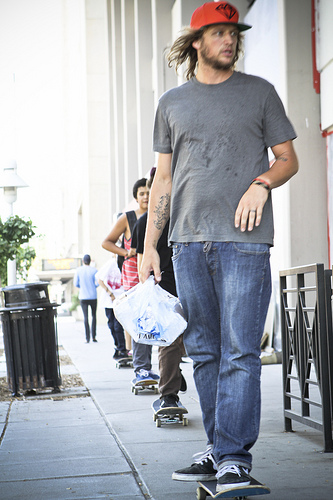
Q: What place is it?
A: It is a city.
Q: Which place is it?
A: It is a city.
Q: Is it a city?
A: Yes, it is a city.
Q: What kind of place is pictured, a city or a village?
A: It is a city.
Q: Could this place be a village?
A: No, it is a city.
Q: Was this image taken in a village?
A: No, the picture was taken in a city.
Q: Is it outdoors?
A: Yes, it is outdoors.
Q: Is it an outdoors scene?
A: Yes, it is outdoors.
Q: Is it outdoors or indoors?
A: It is outdoors.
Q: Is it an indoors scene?
A: No, it is outdoors.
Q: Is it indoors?
A: No, it is outdoors.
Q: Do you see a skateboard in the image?
A: Yes, there is a skateboard.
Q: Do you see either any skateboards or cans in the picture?
A: Yes, there is a skateboard.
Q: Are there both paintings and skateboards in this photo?
A: No, there is a skateboard but no paintings.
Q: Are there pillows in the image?
A: No, there are no pillows.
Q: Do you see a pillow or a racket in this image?
A: No, there are no pillows or rackets.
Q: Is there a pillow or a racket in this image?
A: No, there are no pillows or rackets.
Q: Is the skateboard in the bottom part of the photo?
A: Yes, the skateboard is in the bottom of the image.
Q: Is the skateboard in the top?
A: No, the skateboard is in the bottom of the image.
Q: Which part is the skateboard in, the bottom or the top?
A: The skateboard is in the bottom of the image.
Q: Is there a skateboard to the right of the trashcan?
A: Yes, there is a skateboard to the right of the trashcan.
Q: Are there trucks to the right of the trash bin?
A: No, there is a skateboard to the right of the trash bin.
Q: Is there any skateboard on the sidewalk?
A: Yes, there is a skateboard on the sidewalk.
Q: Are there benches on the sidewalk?
A: No, there is a skateboard on the sidewalk.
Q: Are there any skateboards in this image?
A: Yes, there is a skateboard.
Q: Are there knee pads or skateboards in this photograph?
A: Yes, there is a skateboard.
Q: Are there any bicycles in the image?
A: No, there are no bicycles.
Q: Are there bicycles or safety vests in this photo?
A: No, there are no bicycles or safety vests.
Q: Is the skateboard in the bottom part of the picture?
A: Yes, the skateboard is in the bottom of the image.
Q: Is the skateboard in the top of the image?
A: No, the skateboard is in the bottom of the image.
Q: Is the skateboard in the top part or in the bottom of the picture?
A: The skateboard is in the bottom of the image.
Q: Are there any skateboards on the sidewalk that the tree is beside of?
A: Yes, there is a skateboard on the side walk.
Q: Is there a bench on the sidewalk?
A: No, there is a skateboard on the sidewalk.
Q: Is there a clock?
A: No, there are no clocks.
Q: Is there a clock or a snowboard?
A: No, there are no clocks or snowboards.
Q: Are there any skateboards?
A: Yes, there is a skateboard.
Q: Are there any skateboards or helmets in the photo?
A: Yes, there is a skateboard.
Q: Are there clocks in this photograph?
A: No, there are no clocks.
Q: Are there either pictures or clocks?
A: No, there are no clocks or pictures.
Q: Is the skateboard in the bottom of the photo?
A: Yes, the skateboard is in the bottom of the image.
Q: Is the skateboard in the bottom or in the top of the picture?
A: The skateboard is in the bottom of the image.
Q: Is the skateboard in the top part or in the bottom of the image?
A: The skateboard is in the bottom of the image.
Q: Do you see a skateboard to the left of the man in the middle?
A: Yes, there is a skateboard to the left of the man.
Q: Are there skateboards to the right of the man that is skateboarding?
A: No, the skateboard is to the left of the man.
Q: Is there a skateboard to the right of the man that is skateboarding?
A: No, the skateboard is to the left of the man.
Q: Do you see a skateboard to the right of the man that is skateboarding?
A: No, the skateboard is to the left of the man.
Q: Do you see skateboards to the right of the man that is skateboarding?
A: No, the skateboard is to the left of the man.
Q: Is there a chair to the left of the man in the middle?
A: No, there is a skateboard to the left of the man.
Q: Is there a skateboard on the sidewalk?
A: Yes, there is a skateboard on the sidewalk.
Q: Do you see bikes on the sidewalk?
A: No, there is a skateboard on the sidewalk.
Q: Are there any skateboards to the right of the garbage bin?
A: Yes, there is a skateboard to the right of the garbage bin.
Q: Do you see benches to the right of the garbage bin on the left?
A: No, there is a skateboard to the right of the trash can.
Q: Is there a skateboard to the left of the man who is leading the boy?
A: Yes, there is a skateboard to the left of the man.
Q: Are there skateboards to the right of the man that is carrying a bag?
A: No, the skateboard is to the left of the man.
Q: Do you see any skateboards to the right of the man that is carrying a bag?
A: No, the skateboard is to the left of the man.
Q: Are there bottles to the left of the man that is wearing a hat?
A: No, there is a skateboard to the left of the man.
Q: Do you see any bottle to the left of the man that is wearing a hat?
A: No, there is a skateboard to the left of the man.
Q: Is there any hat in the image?
A: Yes, there is a hat.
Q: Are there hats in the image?
A: Yes, there is a hat.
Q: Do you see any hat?
A: Yes, there is a hat.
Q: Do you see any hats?
A: Yes, there is a hat.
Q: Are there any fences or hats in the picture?
A: Yes, there is a hat.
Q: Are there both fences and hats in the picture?
A: Yes, there are both a hat and a fence.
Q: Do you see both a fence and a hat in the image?
A: Yes, there are both a hat and a fence.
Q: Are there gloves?
A: No, there are no gloves.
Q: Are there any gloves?
A: No, there are no gloves.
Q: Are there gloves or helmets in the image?
A: No, there are no gloves or helmets.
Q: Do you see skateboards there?
A: Yes, there is a skateboard.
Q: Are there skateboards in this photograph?
A: Yes, there is a skateboard.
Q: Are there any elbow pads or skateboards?
A: Yes, there is a skateboard.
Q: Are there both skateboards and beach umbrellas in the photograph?
A: No, there is a skateboard but no beach umbrellas.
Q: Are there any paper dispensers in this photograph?
A: No, there are no paper dispensers.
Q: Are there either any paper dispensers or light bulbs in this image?
A: No, there are no paper dispensers or light bulbs.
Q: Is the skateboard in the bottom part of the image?
A: Yes, the skateboard is in the bottom of the image.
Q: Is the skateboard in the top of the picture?
A: No, the skateboard is in the bottom of the image.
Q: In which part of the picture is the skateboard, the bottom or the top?
A: The skateboard is in the bottom of the image.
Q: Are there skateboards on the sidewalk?
A: Yes, there is a skateboard on the sidewalk.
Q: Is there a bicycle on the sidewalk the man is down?
A: No, there is a skateboard on the side walk.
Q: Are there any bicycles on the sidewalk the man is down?
A: No, there is a skateboard on the side walk.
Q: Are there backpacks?
A: Yes, there is a backpack.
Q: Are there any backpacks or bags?
A: Yes, there is a backpack.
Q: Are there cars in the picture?
A: No, there are no cars.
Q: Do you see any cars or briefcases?
A: No, there are no cars or briefcases.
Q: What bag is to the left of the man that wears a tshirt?
A: The bag is a backpack.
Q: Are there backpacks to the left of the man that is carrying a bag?
A: Yes, there is a backpack to the left of the man.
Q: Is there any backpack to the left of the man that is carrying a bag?
A: Yes, there is a backpack to the left of the man.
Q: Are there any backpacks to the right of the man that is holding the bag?
A: No, the backpack is to the left of the man.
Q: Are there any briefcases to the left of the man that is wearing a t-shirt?
A: No, there is a backpack to the left of the man.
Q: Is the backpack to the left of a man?
A: Yes, the backpack is to the left of a man.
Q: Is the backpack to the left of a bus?
A: No, the backpack is to the left of a man.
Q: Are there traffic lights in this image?
A: No, there are no traffic lights.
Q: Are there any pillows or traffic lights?
A: No, there are no traffic lights or pillows.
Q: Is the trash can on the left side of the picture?
A: Yes, the trash can is on the left of the image.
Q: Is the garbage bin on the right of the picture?
A: No, the garbage bin is on the left of the image.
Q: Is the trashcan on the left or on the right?
A: The trashcan is on the left of the image.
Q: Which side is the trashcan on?
A: The trashcan is on the left of the image.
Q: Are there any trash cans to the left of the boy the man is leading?
A: Yes, there is a trash can to the left of the boy.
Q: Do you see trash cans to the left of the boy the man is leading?
A: Yes, there is a trash can to the left of the boy.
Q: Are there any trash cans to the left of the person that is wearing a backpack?
A: Yes, there is a trash can to the left of the boy.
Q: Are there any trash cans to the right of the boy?
A: No, the trash can is to the left of the boy.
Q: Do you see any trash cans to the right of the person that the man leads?
A: No, the trash can is to the left of the boy.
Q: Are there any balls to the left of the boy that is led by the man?
A: No, there is a trash can to the left of the boy.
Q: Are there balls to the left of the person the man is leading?
A: No, there is a trash can to the left of the boy.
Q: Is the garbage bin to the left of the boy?
A: Yes, the garbage bin is to the left of the boy.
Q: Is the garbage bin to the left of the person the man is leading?
A: Yes, the garbage bin is to the left of the boy.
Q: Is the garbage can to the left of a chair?
A: No, the garbage can is to the left of the boy.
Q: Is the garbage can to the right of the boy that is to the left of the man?
A: No, the garbage can is to the left of the boy.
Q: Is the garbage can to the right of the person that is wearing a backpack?
A: No, the garbage can is to the left of the boy.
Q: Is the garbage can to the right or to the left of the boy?
A: The garbage can is to the left of the boy.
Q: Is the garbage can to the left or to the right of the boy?
A: The garbage can is to the left of the boy.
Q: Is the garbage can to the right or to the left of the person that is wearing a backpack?
A: The garbage can is to the left of the boy.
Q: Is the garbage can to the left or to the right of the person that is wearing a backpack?
A: The garbage can is to the left of the boy.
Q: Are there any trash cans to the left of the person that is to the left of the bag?
A: Yes, there is a trash can to the left of the person.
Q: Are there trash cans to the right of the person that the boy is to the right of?
A: No, the trash can is to the left of the person.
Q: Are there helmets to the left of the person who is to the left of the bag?
A: No, there is a trash can to the left of the person.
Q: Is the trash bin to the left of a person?
A: Yes, the trash bin is to the left of a person.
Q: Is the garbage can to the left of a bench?
A: No, the garbage can is to the left of a person.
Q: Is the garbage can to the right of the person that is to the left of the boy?
A: No, the garbage can is to the left of the person.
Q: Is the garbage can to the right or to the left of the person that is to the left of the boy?
A: The garbage can is to the left of the person.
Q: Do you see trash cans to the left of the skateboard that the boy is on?
A: Yes, there is a trash can to the left of the skateboard.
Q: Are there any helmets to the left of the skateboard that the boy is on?
A: No, there is a trash can to the left of the skateboard.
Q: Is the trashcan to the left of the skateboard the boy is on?
A: Yes, the trashcan is to the left of the skateboard.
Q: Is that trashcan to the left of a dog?
A: No, the trashcan is to the left of the skateboard.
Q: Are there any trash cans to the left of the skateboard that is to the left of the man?
A: Yes, there is a trash can to the left of the skateboard.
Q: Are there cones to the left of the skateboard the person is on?
A: No, there is a trash can to the left of the skateboard.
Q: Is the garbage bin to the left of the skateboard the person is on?
A: Yes, the garbage bin is to the left of the skateboard.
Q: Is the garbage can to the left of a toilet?
A: No, the garbage can is to the left of the skateboard.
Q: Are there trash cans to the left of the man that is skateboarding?
A: Yes, there is a trash can to the left of the man.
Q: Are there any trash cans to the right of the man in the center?
A: No, the trash can is to the left of the man.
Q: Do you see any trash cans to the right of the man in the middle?
A: No, the trash can is to the left of the man.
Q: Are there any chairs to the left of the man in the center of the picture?
A: No, there is a trash can to the left of the man.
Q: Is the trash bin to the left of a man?
A: Yes, the trash bin is to the left of a man.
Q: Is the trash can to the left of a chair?
A: No, the trash can is to the left of a man.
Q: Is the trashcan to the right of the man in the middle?
A: No, the trashcan is to the left of the man.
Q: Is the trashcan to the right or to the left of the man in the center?
A: The trashcan is to the left of the man.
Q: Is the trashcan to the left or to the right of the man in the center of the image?
A: The trashcan is to the left of the man.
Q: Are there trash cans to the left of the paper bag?
A: Yes, there is a trash can to the left of the bag.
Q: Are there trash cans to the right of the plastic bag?
A: No, the trash can is to the left of the bag.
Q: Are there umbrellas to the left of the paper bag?
A: No, there is a trash can to the left of the bag.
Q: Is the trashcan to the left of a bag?
A: Yes, the trashcan is to the left of a bag.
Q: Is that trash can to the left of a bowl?
A: No, the trash can is to the left of a bag.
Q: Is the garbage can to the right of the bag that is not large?
A: No, the garbage can is to the left of the bag.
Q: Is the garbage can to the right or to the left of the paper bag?
A: The garbage can is to the left of the bag.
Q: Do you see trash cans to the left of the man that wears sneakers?
A: Yes, there is a trash can to the left of the man.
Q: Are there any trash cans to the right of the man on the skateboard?
A: No, the trash can is to the left of the man.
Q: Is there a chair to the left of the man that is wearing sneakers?
A: No, there is a trash can to the left of the man.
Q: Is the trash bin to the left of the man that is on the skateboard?
A: Yes, the trash bin is to the left of the man.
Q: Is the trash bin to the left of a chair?
A: No, the trash bin is to the left of the man.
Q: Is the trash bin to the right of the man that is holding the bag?
A: No, the trash bin is to the left of the man.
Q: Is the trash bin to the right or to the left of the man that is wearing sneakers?
A: The trash bin is to the left of the man.